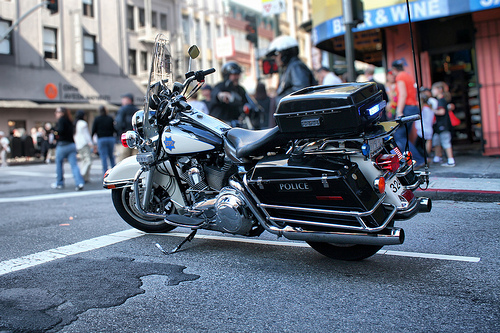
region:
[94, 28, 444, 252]
police motorcycle parked in the road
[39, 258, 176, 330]
pavement has been patched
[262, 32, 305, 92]
police officer behind the bike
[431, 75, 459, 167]
child on the sidewalk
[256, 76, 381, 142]
black box on the back of the bike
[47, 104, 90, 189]
person crossing the street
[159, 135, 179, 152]
police emblem on side of bike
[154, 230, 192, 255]
kickstand is down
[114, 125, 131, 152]
red light on the front of the bike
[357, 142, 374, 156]
blue light on the back of the bike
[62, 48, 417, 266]
motorcycle on the road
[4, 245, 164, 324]
dark part of road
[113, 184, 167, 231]
front wheel of bike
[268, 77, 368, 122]
seat of the bike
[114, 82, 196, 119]
handlebar of the bike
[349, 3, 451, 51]
sign for the store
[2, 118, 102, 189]
the people are walking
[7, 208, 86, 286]
white stripe on road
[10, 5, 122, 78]
windows on the building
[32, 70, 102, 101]
sign for the store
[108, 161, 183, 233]
the tire of a motorcycle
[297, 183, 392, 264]
the tire of a motorcycle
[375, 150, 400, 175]
the rear light of a motorcycle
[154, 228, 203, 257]
the kickstand of a motorcycle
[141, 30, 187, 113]
the windshield of a motorcycle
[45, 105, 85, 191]
a person crossing a street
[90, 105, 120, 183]
a person crossing a street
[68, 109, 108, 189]
a person crossing a street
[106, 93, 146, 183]
a person crossing a street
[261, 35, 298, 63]
a man with a white helmet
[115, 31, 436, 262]
the motorcycle is on the street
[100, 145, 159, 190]
the fender is made of metal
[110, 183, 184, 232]
the tire is black in color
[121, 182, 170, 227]
the rim is made of metal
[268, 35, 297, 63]
the policeman is wearing a helmet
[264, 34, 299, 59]
the helmet is made of plastic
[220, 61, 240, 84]
the man is wearing a helmet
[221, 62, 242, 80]
the helmet is made of plastic